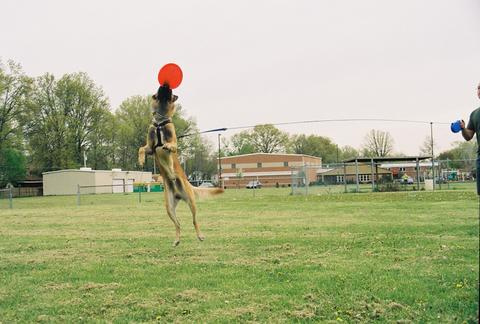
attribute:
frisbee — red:
[156, 62, 188, 91]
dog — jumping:
[133, 82, 204, 248]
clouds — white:
[8, 6, 473, 70]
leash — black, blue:
[171, 116, 461, 147]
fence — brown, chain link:
[8, 175, 158, 208]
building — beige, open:
[39, 169, 156, 198]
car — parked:
[244, 176, 266, 191]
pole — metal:
[212, 130, 225, 189]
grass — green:
[63, 227, 124, 261]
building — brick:
[214, 151, 327, 187]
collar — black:
[146, 113, 180, 128]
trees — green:
[3, 62, 201, 180]